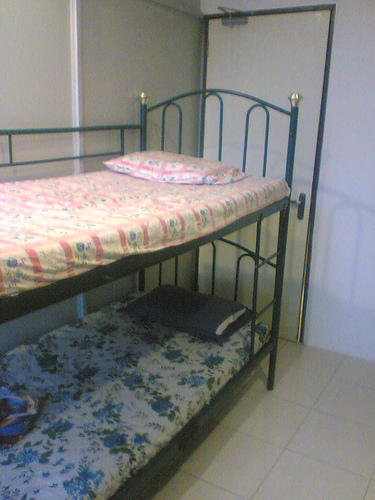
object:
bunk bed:
[0, 86, 302, 499]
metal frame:
[138, 84, 295, 391]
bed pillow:
[100, 150, 249, 187]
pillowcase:
[105, 148, 243, 183]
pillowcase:
[123, 282, 257, 340]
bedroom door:
[197, 5, 336, 344]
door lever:
[289, 190, 306, 221]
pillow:
[112, 284, 259, 346]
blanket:
[0, 383, 41, 450]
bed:
[0, 283, 274, 499]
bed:
[0, 148, 292, 301]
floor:
[128, 337, 375, 499]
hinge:
[214, 5, 249, 28]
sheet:
[0, 153, 291, 299]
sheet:
[0, 292, 272, 500]